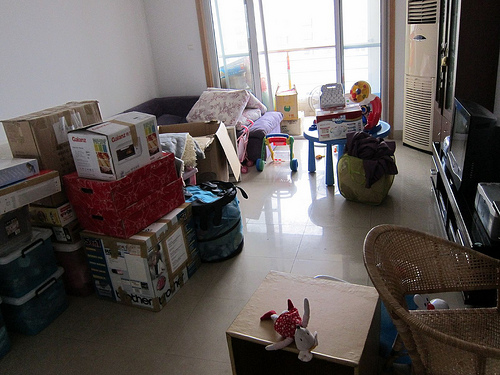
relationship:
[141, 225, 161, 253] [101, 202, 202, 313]
tape on box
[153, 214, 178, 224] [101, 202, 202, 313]
tape on box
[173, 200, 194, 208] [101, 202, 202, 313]
tape on box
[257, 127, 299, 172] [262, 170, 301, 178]
toy on ground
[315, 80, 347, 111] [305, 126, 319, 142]
item piled on blue table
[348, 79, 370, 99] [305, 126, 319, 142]
item piled on blue table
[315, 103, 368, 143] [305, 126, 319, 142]
item piled on blue table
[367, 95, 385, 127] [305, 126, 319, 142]
item piled on blue table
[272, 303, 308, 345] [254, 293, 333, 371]
shirt on doll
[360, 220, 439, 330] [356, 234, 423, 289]
back of chair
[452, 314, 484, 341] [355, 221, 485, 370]
seat of chair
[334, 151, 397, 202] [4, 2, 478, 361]
hamper in room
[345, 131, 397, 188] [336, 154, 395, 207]
clothes on top of hamper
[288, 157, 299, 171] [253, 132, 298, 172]
wheel on walker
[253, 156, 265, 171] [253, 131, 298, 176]
wheel on walker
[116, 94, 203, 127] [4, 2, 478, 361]
sofa in room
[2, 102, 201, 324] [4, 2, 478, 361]
boxes in room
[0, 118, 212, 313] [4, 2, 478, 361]
bins in room